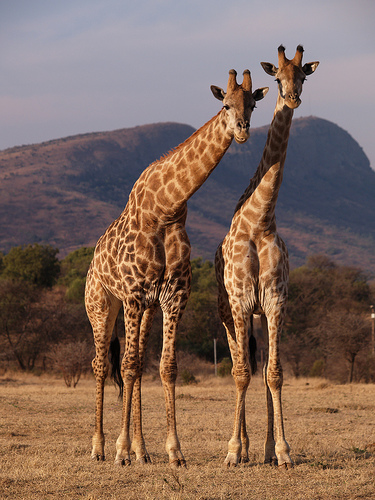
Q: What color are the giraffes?
A: Brown.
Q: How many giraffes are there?
A: 2.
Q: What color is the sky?
A: Blue.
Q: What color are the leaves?
A: Green.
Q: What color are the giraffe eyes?
A: Black.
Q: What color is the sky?
A: Blue.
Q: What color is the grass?
A: Brown.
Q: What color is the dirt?
A: Brown.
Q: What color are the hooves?
A: Brown.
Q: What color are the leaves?
A: Green.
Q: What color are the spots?
A: Brown.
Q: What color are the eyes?
A: Black.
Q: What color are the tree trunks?
A: Brown.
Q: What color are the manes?
A: Brown.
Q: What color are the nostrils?
A: Brown.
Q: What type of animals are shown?
A: Giraffes.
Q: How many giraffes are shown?
A: Two.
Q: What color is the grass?
A: Brown.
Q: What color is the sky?
A: Blue.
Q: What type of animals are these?
A: Giraffes.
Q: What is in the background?
A: Mountains.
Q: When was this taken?
A: Daytime.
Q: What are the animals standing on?
A: The grass.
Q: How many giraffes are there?
A: Two.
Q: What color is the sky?
A: Blue.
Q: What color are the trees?
A: Green.